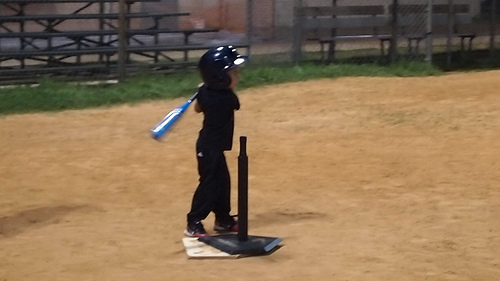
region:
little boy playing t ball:
[131, 40, 339, 270]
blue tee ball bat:
[147, 96, 197, 147]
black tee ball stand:
[188, 128, 290, 267]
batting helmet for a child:
[193, 36, 250, 87]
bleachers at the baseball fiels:
[14, 11, 223, 90]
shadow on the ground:
[13, 188, 97, 248]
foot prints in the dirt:
[359, 129, 461, 259]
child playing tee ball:
[134, 39, 288, 270]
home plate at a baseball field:
[185, 231, 285, 266]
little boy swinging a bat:
[142, 34, 284, 259]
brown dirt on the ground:
[0, 67, 498, 279]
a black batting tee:
[227, 131, 252, 239]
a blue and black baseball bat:
[147, 79, 205, 146]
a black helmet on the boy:
[194, 39, 249, 94]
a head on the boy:
[194, 39, 258, 92]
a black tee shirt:
[193, 82, 250, 151]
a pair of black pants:
[184, 149, 239, 225]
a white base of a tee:
[176, 223, 285, 268]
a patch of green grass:
[0, 51, 457, 120]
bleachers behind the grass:
[0, 3, 259, 88]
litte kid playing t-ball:
[136, 43, 313, 263]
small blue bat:
[143, 86, 205, 138]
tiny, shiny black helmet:
[191, 38, 251, 91]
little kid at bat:
[132, 28, 300, 270]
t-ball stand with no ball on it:
[230, 133, 264, 248]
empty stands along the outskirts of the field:
[3, 3, 268, 72]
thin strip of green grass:
[4, 54, 438, 99]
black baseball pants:
[188, 147, 229, 230]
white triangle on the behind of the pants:
[198, 152, 203, 158]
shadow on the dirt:
[231, 199, 317, 231]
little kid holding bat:
[193, 40, 272, 278]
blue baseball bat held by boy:
[131, 90, 201, 152]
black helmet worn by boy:
[190, 37, 256, 89]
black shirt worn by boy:
[195, 81, 240, 148]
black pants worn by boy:
[189, 141, 236, 222]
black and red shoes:
[185, 212, 236, 236]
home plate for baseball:
[167, 233, 249, 277]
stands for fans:
[47, 20, 179, 77]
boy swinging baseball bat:
[123, 65, 263, 159]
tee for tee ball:
[225, 140, 288, 264]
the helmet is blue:
[192, 41, 249, 85]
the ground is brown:
[315, 119, 451, 254]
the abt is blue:
[147, 95, 185, 139]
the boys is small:
[167, 52, 248, 234]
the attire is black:
[187, 93, 242, 218]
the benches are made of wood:
[40, 10, 177, 55]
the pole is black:
[234, 132, 256, 244]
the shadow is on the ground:
[12, 200, 59, 226]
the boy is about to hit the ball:
[175, 57, 238, 232]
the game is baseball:
[1, 33, 495, 276]